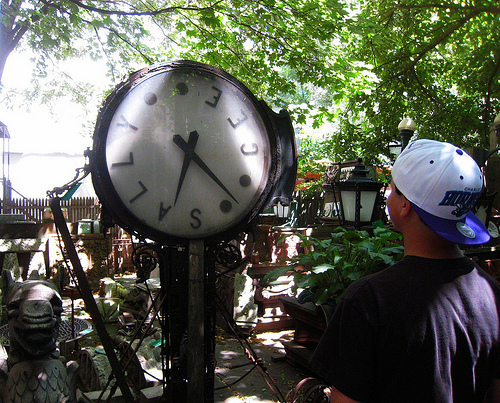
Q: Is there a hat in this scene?
A: Yes, there is a hat.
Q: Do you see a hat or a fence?
A: Yes, there is a hat.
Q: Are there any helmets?
A: No, there are no helmets.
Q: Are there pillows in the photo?
A: No, there are no pillows.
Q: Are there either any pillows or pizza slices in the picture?
A: No, there are no pillows or pizza slices.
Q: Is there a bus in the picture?
A: No, there are no buses.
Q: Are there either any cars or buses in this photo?
A: No, there are no buses or cars.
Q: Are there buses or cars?
A: No, there are no buses or cars.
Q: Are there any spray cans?
A: No, there are no spray cans.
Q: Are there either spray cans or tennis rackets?
A: No, there are no spray cans or tennis rackets.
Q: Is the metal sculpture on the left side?
A: Yes, the sculpture is on the left of the image.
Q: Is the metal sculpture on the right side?
A: No, the sculpture is on the left of the image.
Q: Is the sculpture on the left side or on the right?
A: The sculpture is on the left of the image.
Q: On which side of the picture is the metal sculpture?
A: The sculpture is on the left of the image.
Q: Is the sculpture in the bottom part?
A: Yes, the sculpture is in the bottom of the image.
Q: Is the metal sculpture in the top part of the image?
A: No, the sculpture is in the bottom of the image.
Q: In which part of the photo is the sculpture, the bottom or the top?
A: The sculpture is in the bottom of the image.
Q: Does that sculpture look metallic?
A: Yes, the sculpture is metallic.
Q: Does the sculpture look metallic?
A: Yes, the sculpture is metallic.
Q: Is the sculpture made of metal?
A: Yes, the sculpture is made of metal.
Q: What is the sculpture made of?
A: The sculpture is made of metal.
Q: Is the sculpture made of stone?
A: No, the sculpture is made of metal.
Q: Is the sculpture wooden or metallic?
A: The sculpture is metallic.